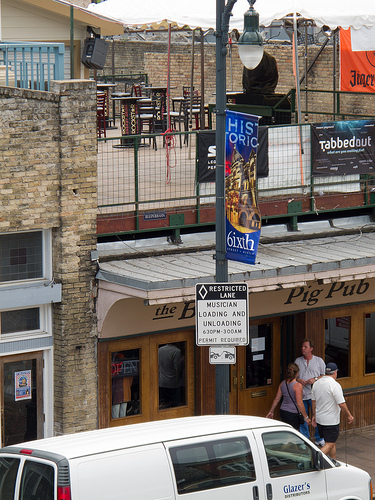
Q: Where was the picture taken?
A: In a city.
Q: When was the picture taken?
A: Daytime.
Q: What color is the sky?
A: White.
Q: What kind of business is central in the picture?
A: A bar.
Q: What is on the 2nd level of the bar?
A: The rooftop.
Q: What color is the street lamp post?
A: Green.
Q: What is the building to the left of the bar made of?
A: Brick.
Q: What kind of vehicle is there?
A: A van.